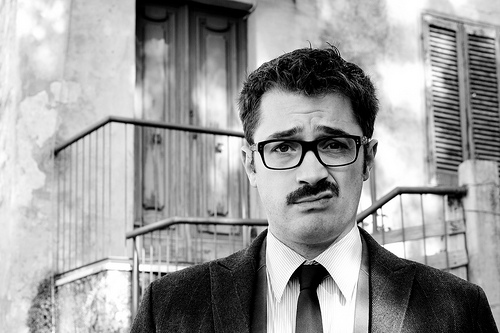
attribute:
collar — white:
[261, 222, 366, 307]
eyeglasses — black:
[249, 127, 374, 169]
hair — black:
[283, 176, 348, 198]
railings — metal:
[46, 112, 475, 300]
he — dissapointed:
[152, 50, 495, 330]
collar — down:
[266, 222, 361, 306]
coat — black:
[129, 256, 494, 331]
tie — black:
[291, 263, 333, 330]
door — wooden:
[186, 0, 250, 261]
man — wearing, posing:
[131, 39, 498, 331]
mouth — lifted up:
[289, 184, 339, 212]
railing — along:
[363, 182, 478, 277]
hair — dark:
[219, 50, 385, 150]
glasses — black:
[241, 121, 378, 198]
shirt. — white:
[260, 238, 362, 331]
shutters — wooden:
[423, 15, 497, 167]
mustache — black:
[279, 180, 343, 209]